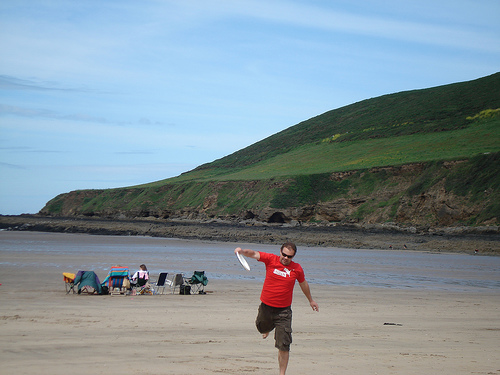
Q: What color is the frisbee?
A: White.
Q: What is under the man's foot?
A: Sand.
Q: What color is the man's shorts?
A: Brown.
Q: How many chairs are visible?
A: Seven.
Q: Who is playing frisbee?
A: The man.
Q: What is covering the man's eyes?
A: Sunglasses.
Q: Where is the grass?
A: Hillside.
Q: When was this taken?
A: Daytime.